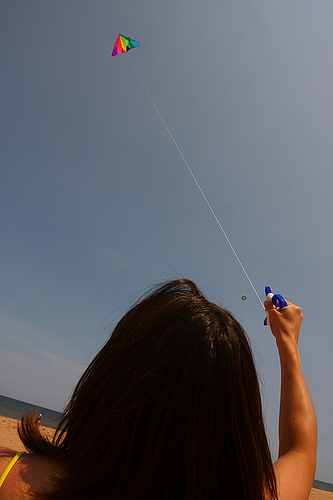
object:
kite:
[110, 32, 138, 60]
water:
[0, 395, 332, 491]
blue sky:
[0, 0, 332, 487]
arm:
[263, 328, 319, 499]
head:
[51, 279, 287, 498]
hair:
[14, 278, 279, 498]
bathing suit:
[1, 448, 23, 481]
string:
[120, 52, 265, 310]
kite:
[239, 294, 247, 302]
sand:
[0, 417, 332, 499]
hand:
[262, 290, 303, 349]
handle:
[259, 284, 286, 329]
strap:
[0, 445, 26, 487]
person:
[0, 275, 318, 499]